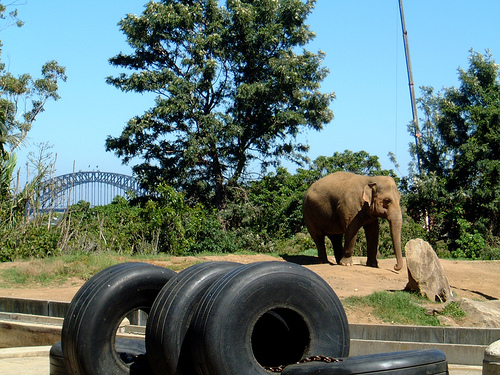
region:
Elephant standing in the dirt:
[303, 172, 403, 271]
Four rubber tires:
[57, 260, 447, 374]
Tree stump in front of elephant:
[403, 235, 453, 306]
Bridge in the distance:
[21, 167, 153, 214]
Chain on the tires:
[271, 349, 342, 368]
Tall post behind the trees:
[394, 0, 431, 234]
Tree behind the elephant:
[106, 2, 336, 233]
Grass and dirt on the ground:
[0, 253, 498, 323]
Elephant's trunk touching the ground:
[390, 210, 405, 275]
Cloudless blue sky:
[0, 0, 498, 192]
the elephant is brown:
[288, 161, 414, 282]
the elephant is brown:
[286, 164, 411, 273]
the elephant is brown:
[283, 157, 405, 281]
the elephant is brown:
[296, 164, 416, 276]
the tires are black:
[37, 247, 339, 373]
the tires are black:
[60, 245, 311, 373]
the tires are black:
[63, 245, 307, 367]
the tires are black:
[63, 250, 289, 362]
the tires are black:
[75, 225, 348, 372]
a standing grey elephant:
[301, 170, 405, 271]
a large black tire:
[193, 260, 351, 372]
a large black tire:
[283, 350, 448, 374]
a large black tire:
[144, 263, 239, 374]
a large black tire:
[61, 260, 176, 374]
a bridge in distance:
[22, 169, 157, 213]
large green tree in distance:
[114, 2, 336, 192]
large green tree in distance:
[408, 46, 498, 242]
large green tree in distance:
[0, 2, 72, 232]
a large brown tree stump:
[402, 236, 453, 302]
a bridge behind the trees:
[20, 173, 141, 209]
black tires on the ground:
[70, 270, 335, 371]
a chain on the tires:
[256, 350, 341, 370]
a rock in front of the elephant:
[400, 237, 451, 298]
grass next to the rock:
[355, 280, 425, 325]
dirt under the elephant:
[300, 250, 485, 290]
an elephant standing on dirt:
[302, 166, 407, 271]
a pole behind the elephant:
[381, 5, 441, 166]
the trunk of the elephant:
[390, 201, 405, 271]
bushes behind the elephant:
[45, 186, 331, 243]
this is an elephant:
[279, 144, 431, 275]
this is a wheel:
[298, 325, 427, 370]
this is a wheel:
[186, 258, 348, 367]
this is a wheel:
[151, 256, 240, 355]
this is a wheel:
[53, 251, 160, 370]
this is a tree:
[121, 4, 311, 231]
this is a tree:
[1, 11, 54, 252]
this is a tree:
[426, 72, 493, 276]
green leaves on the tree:
[181, 90, 247, 131]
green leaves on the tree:
[450, 124, 499, 211]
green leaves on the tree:
[429, 206, 496, 246]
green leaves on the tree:
[347, 144, 375, 166]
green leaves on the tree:
[262, 161, 294, 220]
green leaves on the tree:
[139, 110, 207, 180]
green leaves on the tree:
[127, 33, 175, 109]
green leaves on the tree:
[193, 30, 259, 103]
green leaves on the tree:
[456, 43, 496, 110]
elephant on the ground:
[249, 154, 464, 291]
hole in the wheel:
[237, 281, 343, 366]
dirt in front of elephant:
[438, 261, 493, 306]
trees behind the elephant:
[100, 189, 245, 249]